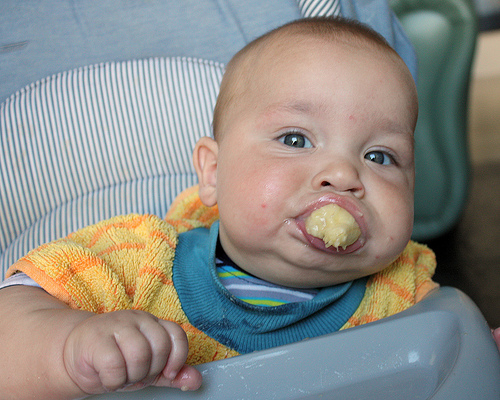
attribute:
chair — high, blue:
[8, 260, 498, 395]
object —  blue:
[79, 285, 499, 398]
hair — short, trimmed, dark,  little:
[206, 17, 421, 141]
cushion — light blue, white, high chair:
[0, 57, 222, 280]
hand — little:
[81, 318, 165, 380]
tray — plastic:
[428, 279, 440, 391]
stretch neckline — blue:
[172, 222, 367, 353]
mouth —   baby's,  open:
[289, 195, 371, 256]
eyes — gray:
[272, 123, 403, 169]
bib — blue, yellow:
[5, 185, 439, 370]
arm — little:
[6, 227, 214, 397]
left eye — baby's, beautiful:
[368, 145, 391, 166]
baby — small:
[0, 15, 438, 397]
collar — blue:
[177, 242, 205, 290]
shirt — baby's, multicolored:
[241, 293, 337, 330]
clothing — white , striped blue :
[5, 52, 231, 272]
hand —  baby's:
[62, 305, 203, 396]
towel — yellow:
[5, 183, 440, 367]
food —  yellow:
[303, 205, 363, 252]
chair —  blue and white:
[7, 3, 423, 307]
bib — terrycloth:
[4, 180, 458, 362]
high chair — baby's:
[7, 26, 491, 397]